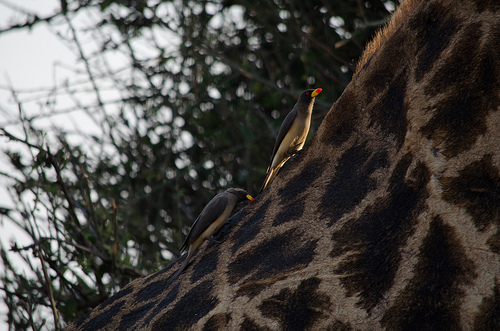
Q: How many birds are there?
A: 2.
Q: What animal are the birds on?
A: Giraffe.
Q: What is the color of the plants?
A: Green.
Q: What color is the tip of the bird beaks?
A: Red.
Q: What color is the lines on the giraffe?
A: Tan.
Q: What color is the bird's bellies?
A: Tan.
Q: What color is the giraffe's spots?
A: Brown.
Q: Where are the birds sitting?
A: Back of giraffe.